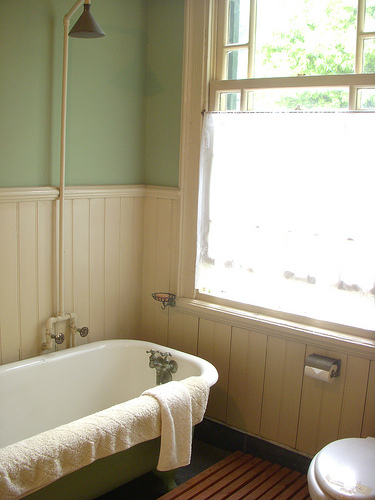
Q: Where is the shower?
A: Above the tub.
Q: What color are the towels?
A: White.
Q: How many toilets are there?
A: One.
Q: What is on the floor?
A: Wood.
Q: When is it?
A: Day time.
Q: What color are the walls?
A: White and green.